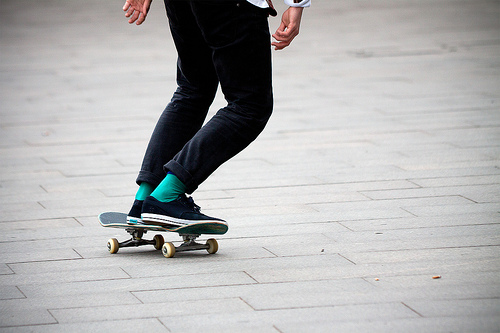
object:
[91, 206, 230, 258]
skateboard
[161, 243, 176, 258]
wheel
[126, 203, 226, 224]
foot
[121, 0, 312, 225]
person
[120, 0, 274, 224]
leg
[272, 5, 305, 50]
hand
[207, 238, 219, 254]
wheel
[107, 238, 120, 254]
wheel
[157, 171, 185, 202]
sock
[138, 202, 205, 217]
sneaker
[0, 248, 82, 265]
brick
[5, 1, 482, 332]
walkway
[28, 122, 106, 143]
tile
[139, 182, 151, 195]
sock